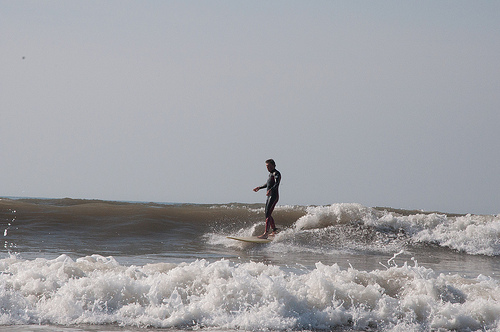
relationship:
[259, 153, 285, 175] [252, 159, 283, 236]
head of a male surfer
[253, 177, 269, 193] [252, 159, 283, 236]
arm of male surfer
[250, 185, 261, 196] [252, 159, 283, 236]
hand of male surfer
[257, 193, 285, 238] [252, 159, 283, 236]
legs of male surfer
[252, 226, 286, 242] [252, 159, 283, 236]
feet of male surfer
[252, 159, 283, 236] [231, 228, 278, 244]
male surfer on long ivory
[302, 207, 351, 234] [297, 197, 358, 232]
crest of a wave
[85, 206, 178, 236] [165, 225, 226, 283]
gray ocean of water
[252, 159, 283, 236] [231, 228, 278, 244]
male surfer standing on long ivory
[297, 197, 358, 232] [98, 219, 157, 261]
wave formed in ocean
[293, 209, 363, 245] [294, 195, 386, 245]
breaking wave on shoreline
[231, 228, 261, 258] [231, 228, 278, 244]
long ivory of long ivory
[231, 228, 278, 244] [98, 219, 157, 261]
long ivory in ocean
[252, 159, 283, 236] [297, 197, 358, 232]
male surfer riding wave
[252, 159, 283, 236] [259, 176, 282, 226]
male surfer wearing wetsuit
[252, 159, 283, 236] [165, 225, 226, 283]
male surfer looking at water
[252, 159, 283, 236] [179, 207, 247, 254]
male surfer watching wave break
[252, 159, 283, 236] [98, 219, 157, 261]
male surfer in ocean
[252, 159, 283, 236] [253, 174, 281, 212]
male surfer wearing wet suit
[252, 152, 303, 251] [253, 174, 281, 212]
male surfer wearing wet suit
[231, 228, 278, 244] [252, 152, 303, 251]
long ivory ridden by male surfer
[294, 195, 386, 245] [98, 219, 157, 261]
waves in ocean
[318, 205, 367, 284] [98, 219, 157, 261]
waves in ocean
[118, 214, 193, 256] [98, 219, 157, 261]
white and brown waves in ocean